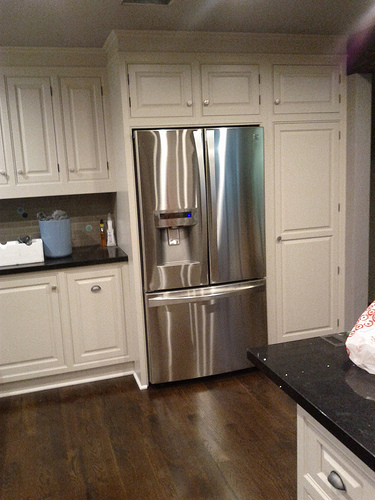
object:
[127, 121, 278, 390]
fridge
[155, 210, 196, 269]
dispenser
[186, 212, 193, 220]
light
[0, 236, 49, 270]
container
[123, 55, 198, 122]
cupboard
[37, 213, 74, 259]
container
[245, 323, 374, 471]
countertop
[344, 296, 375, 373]
bag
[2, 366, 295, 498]
floors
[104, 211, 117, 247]
bottles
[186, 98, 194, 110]
handle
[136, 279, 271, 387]
freezer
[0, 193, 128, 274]
backsplash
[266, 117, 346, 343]
cabinet